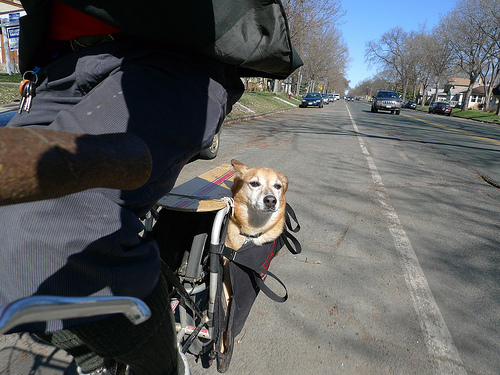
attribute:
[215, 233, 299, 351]
dog carrier — black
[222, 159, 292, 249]
dog — brown, beige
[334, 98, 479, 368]
line — white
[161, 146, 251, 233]
board — tan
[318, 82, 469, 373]
street — ordinary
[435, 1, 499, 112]
tree — bare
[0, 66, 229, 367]
pants — grey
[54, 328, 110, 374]
socks — green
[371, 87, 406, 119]
jeep — dark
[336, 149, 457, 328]
line — white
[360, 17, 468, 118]
tree — brown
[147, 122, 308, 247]
skateboard — wooden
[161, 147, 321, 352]
bike rack — modified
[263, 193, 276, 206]
nose — black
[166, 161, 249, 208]
stripe — red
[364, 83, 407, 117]
van — blue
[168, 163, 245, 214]
stripe — red